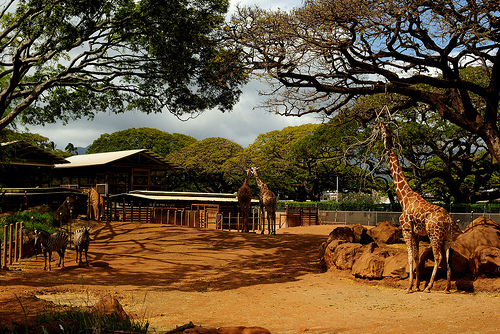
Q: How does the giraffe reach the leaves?
A: Long neck.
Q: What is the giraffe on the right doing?
A: Eating.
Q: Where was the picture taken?
A: Zoo.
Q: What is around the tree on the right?
A: Rocks.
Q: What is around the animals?
A: Fence.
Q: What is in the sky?
A: Clouds.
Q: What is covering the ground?
A: Dirt.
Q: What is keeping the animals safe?
A: Fence.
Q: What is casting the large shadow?
A: Tree.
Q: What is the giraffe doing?
A: Standing alone.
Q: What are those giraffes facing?
A: Some very large trees.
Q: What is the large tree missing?
A: Several leaves.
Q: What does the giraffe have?
A: A tail.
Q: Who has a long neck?
A: A giraffe.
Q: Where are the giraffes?
A: On the farm.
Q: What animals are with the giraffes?
A: Goats.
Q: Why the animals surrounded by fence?
A: To prevent them to get away.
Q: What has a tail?
A: The giraffe.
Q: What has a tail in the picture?
A: The giraffe.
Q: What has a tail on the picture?
A: The giraffe.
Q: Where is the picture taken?
A: Zoo.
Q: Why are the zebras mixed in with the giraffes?
A: They get along.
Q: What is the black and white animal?
A: Zebra.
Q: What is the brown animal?
A: Giraffe.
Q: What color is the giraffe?
A: Brown.